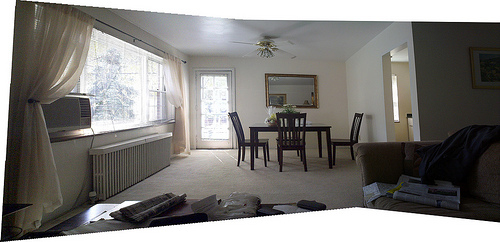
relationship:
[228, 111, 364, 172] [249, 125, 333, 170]
dining set accompany table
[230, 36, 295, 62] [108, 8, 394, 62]
fan on ceiling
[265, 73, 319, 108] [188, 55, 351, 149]
mirror on wall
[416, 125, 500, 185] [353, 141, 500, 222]
blanket on couch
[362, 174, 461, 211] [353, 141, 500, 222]
papers are on couch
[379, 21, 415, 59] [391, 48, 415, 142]
archway to another room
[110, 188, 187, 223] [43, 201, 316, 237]
newspaper lays on table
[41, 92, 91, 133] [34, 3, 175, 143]
air conditioner in window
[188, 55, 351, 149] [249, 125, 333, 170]
wall beside table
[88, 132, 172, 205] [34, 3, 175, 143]
heater under window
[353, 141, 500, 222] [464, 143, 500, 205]
couch has back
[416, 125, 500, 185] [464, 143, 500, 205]
blanket on back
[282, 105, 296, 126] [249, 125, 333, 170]
flowers are on table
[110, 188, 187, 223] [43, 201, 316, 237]
newspaper on table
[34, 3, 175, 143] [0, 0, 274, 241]
window on left side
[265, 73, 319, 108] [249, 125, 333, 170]
mirror over table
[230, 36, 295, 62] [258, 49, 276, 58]
fan has lights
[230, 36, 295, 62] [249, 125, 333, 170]
fan over table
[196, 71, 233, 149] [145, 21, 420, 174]
door in dining room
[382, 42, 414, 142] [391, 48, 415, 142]
passageway leads to another room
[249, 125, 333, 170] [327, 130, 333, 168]
table has stand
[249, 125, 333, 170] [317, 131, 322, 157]
table has stand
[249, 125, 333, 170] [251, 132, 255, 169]
table has stand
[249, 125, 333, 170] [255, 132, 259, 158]
table has stand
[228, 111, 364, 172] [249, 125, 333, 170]
dining set has table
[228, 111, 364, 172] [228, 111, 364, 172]
dining set has dining set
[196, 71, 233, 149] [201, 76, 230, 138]
door has window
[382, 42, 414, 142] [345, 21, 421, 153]
passageway in wall